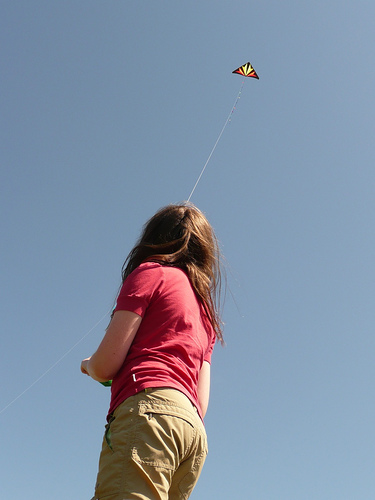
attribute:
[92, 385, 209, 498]
pants — tan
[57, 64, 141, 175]
blue sky — clear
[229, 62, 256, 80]
kite — black, yellow, red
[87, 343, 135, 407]
elbow — bare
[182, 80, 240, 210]
string — white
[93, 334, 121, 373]
arm — bare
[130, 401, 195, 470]
pocket — back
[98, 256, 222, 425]
shirt — red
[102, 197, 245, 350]
hair — brown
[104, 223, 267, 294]
hair — long, dark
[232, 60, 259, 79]
kite — triangular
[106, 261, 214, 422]
shirt — red 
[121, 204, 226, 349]
hair — brown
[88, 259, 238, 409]
shirt — red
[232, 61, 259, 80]
kite — multi-colored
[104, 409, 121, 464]
pocket — side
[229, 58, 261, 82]
kite — black, orange, yellow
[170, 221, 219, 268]
hair — long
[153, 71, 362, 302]
string — white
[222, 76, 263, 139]
tail — long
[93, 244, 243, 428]
shirt — red, tee